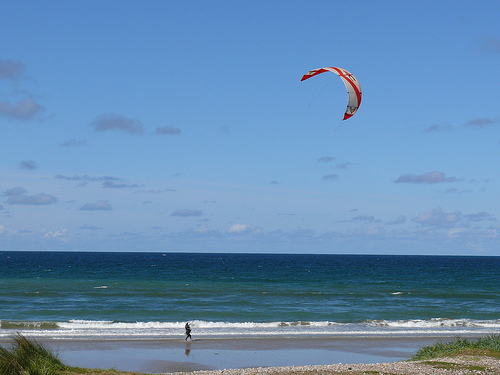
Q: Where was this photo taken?
A: Beach.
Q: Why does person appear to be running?
A: Flying kite.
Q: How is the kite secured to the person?
A: String.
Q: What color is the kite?
A: Red and white.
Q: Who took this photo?
A: Photographer.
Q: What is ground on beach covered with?
A: Sand.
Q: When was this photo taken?
A: Daytime.